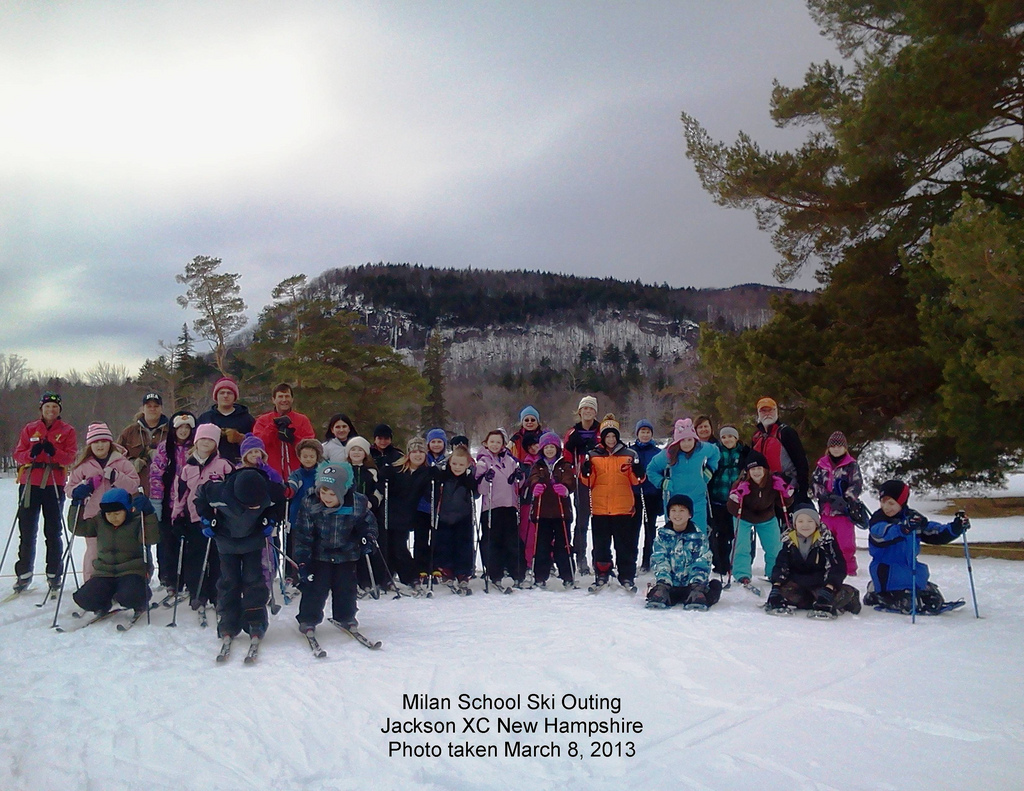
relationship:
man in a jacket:
[2, 391, 79, 592] [17, 421, 81, 479]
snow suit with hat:
[646, 438, 720, 538] [669, 415, 698, 441]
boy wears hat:
[68, 478, 155, 615] [96, 485, 132, 511]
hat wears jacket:
[96, 485, 132, 511] [65, 500, 155, 583]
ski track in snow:
[7, 636, 189, 682] [2, 476, 1023, 789]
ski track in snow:
[68, 704, 146, 788] [2, 476, 1023, 789]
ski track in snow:
[143, 688, 305, 784] [2, 476, 1023, 789]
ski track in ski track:
[391, 642, 448, 783] [602, 615, 986, 786]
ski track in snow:
[602, 615, 986, 786] [2, 476, 1023, 789]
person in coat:
[571, 412, 645, 593] [573, 447, 647, 514]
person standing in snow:
[143, 413, 197, 592] [2, 476, 1023, 789]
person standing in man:
[116, 389, 173, 451] [12, 391, 80, 593]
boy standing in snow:
[67, 483, 161, 620] [2, 476, 1023, 789]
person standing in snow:
[65, 422, 141, 579] [2, 476, 1023, 789]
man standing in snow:
[12, 391, 80, 593] [2, 476, 1023, 789]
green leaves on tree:
[854, 259, 896, 343] [681, 4, 1023, 464]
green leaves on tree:
[185, 253, 243, 340] [166, 241, 246, 369]